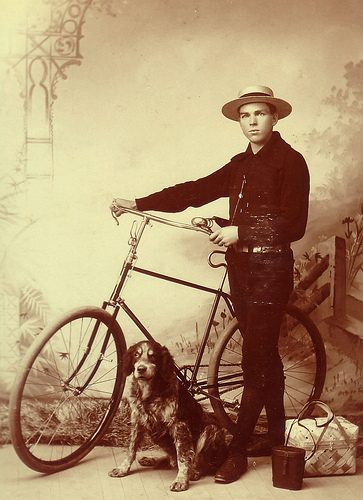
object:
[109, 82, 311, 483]
man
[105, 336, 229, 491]
dog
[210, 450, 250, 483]
shoe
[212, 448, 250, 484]
foot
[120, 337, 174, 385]
head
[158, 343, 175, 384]
ear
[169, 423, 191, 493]
leg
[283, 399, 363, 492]
basket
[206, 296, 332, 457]
tire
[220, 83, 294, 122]
hat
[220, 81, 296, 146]
man's head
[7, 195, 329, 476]
bicycle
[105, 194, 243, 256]
handlebars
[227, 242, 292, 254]
belt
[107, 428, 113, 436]
leaf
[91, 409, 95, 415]
leaf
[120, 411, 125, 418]
leaf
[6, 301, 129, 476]
bicycle wheel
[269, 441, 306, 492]
patch